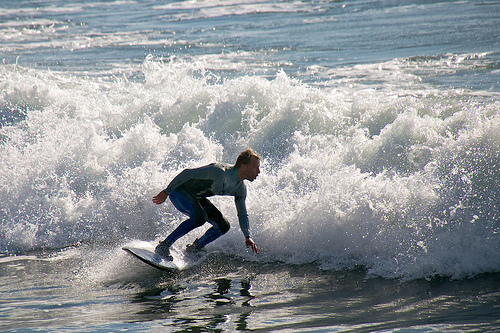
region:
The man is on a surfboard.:
[1, 1, 499, 331]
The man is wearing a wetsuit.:
[99, 126, 400, 289]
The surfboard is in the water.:
[47, 95, 324, 300]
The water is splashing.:
[2, 3, 493, 331]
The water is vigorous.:
[2, 1, 498, 331]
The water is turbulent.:
[0, 0, 499, 330]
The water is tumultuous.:
[1, 2, 499, 332]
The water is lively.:
[1, 0, 498, 331]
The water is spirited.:
[1, 1, 499, 331]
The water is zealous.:
[0, 0, 499, 331]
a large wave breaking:
[1, 68, 492, 277]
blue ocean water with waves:
[2, 0, 495, 330]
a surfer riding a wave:
[122, 150, 256, 267]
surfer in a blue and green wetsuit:
[150, 145, 256, 260]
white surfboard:
[124, 241, 208, 271]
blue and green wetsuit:
[162, 163, 247, 245]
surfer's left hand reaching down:
[235, 185, 257, 250]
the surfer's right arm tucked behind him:
[148, 164, 215, 206]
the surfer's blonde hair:
[234, 148, 261, 164]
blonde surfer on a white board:
[125, 147, 259, 266]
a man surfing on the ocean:
[122, 147, 258, 268]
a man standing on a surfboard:
[150, 150, 260, 257]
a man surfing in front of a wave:
[121, 146, 256, 267]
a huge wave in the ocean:
[0, 55, 499, 280]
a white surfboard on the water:
[124, 238, 208, 269]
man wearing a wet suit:
[157, 163, 247, 245]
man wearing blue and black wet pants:
[168, 185, 229, 245]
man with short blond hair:
[234, 148, 260, 185]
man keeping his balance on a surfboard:
[153, 150, 259, 262]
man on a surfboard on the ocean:
[123, 148, 261, 271]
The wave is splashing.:
[2, 4, 491, 271]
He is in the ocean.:
[21, 1, 485, 271]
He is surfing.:
[102, 146, 310, 299]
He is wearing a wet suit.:
[121, 139, 296, 274]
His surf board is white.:
[108, 204, 207, 293]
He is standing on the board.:
[80, 132, 351, 326]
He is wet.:
[10, 43, 494, 298]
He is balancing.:
[104, 131, 314, 293]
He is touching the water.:
[98, 116, 288, 306]